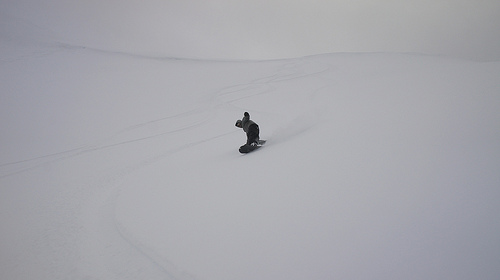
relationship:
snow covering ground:
[297, 57, 483, 263] [16, 6, 496, 278]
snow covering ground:
[297, 57, 483, 263] [19, 62, 486, 274]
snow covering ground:
[297, 57, 483, 263] [22, 86, 498, 273]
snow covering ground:
[297, 57, 483, 263] [4, 37, 485, 269]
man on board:
[235, 112, 260, 148] [238, 138, 269, 154]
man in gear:
[235, 112, 260, 148] [238, 110, 259, 148]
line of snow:
[7, 40, 484, 65] [297, 57, 483, 263]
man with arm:
[231, 110, 263, 153] [241, 115, 250, 120]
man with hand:
[231, 110, 263, 153] [243, 108, 250, 117]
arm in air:
[241, 115, 250, 120] [0, 0, 498, 279]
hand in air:
[243, 108, 250, 117] [0, 0, 498, 279]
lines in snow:
[62, 134, 264, 256] [297, 57, 483, 263]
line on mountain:
[61, 43, 500, 65] [5, 32, 487, 279]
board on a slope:
[238, 138, 269, 154] [24, 11, 474, 101]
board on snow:
[238, 138, 269, 154] [297, 57, 483, 263]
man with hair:
[235, 112, 260, 148] [234, 117, 241, 127]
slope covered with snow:
[24, 11, 474, 101] [297, 57, 483, 263]